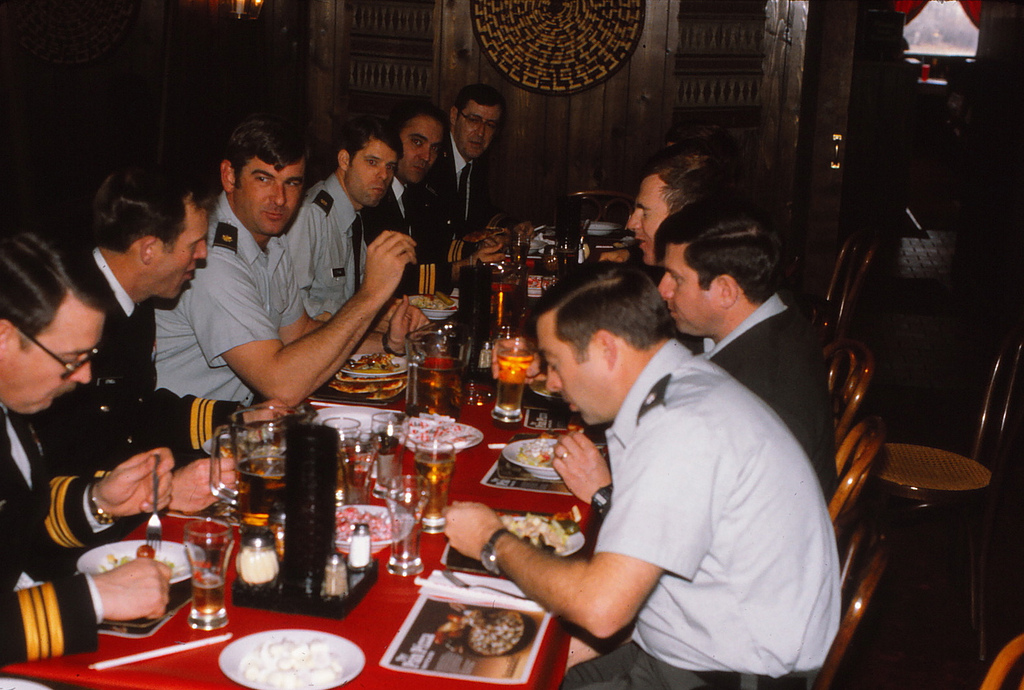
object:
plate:
[0, 220, 655, 690]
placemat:
[378, 509, 585, 684]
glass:
[413, 440, 455, 534]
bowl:
[340, 353, 408, 378]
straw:
[87, 631, 239, 674]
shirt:
[588, 340, 839, 678]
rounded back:
[679, 361, 844, 679]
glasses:
[6, 321, 99, 382]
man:
[0, 230, 173, 670]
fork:
[146, 454, 162, 552]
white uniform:
[154, 191, 305, 409]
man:
[154, 113, 415, 407]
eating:
[441, 271, 838, 690]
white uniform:
[277, 173, 369, 316]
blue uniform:
[29, 244, 242, 476]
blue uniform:
[360, 172, 479, 296]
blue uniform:
[428, 133, 523, 229]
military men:
[0, 83, 534, 667]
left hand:
[441, 501, 504, 560]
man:
[29, 164, 288, 514]